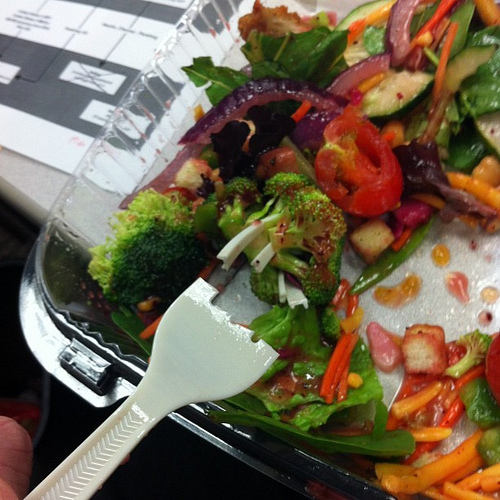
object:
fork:
[0, 247, 303, 498]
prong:
[215, 207, 288, 268]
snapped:
[221, 208, 309, 308]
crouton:
[403, 324, 449, 378]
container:
[0, 4, 500, 493]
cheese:
[399, 372, 451, 433]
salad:
[80, 0, 500, 430]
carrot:
[382, 430, 479, 492]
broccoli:
[91, 191, 196, 300]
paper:
[0, 0, 255, 194]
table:
[0, 141, 118, 263]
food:
[83, 0, 500, 500]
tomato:
[309, 107, 404, 215]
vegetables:
[81, 0, 499, 500]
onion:
[176, 78, 342, 147]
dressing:
[136, 4, 500, 496]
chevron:
[40, 406, 149, 500]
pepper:
[348, 36, 365, 56]